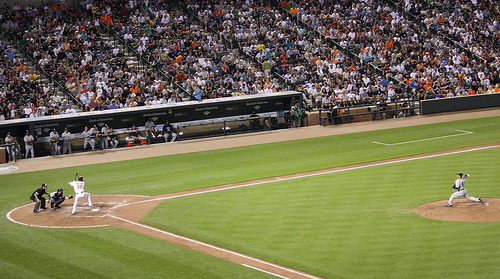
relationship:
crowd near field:
[3, 0, 499, 120] [4, 124, 499, 278]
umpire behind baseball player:
[29, 180, 52, 215] [66, 168, 96, 218]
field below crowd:
[4, 124, 499, 278] [3, 0, 499, 120]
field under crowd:
[4, 124, 499, 278] [3, 0, 499, 120]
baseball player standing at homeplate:
[66, 168, 96, 218] [84, 200, 104, 218]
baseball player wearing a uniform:
[66, 173, 96, 218] [66, 180, 95, 212]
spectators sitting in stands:
[84, 31, 300, 92] [6, 7, 495, 123]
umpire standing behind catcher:
[32, 182, 52, 211] [46, 185, 69, 210]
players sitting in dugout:
[10, 113, 190, 154] [6, 87, 313, 168]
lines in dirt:
[114, 140, 493, 277] [18, 137, 498, 274]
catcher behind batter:
[49, 184, 70, 210] [65, 165, 95, 222]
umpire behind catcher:
[29, 180, 52, 215] [50, 185, 82, 211]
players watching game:
[4, 106, 188, 162] [8, 104, 494, 277]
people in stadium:
[5, 8, 498, 169] [5, 2, 496, 277]